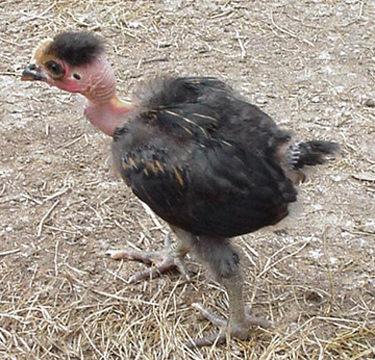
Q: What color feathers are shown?
A: Black.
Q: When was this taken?
A: Daytime.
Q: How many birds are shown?
A: 1.